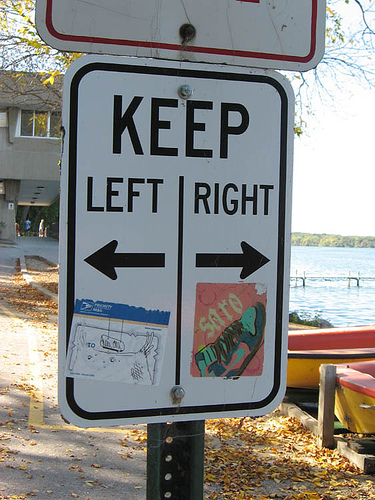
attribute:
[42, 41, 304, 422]
sign — black, white, rectangular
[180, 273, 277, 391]
sticker — red, green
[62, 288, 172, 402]
sticker — white, blue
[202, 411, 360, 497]
leaves — brown, yellow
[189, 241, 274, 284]
arrow — black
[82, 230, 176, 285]
arrow — black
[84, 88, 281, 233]
letters — black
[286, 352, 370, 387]
paint — yellow, red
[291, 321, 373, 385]
boat — yellow, red, yello, plastic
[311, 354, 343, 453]
pole — wooden, brown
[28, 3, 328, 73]
sign — red, white, rectangular